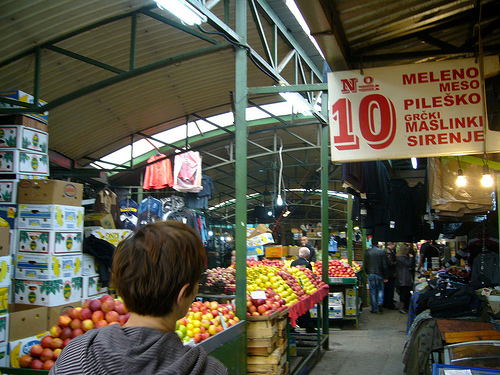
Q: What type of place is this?
A: It is a market.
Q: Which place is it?
A: It is a market.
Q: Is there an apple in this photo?
A: Yes, there are apples.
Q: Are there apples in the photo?
A: Yes, there are apples.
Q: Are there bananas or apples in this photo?
A: Yes, there are apples.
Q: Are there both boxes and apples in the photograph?
A: Yes, there are both apples and a box.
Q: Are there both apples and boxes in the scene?
A: Yes, there are both apples and a box.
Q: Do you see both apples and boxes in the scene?
A: Yes, there are both apples and a box.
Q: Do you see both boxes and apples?
A: Yes, there are both apples and a box.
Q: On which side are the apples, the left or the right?
A: The apples are on the left of the image.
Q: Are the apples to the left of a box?
A: Yes, the apples are to the left of a box.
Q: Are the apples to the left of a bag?
A: No, the apples are to the left of a box.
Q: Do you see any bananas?
A: Yes, there are bananas.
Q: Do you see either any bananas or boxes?
A: Yes, there are bananas.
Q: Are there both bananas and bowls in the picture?
A: No, there are bananas but no bowls.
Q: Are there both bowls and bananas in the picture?
A: No, there are bananas but no bowls.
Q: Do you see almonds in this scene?
A: No, there are no almonds.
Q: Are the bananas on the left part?
A: Yes, the bananas are on the left of the image.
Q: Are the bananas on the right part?
A: No, the bananas are on the left of the image.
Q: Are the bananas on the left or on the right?
A: The bananas are on the left of the image.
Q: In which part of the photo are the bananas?
A: The bananas are on the left of the image.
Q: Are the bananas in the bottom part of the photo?
A: Yes, the bananas are in the bottom of the image.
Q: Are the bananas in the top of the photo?
A: No, the bananas are in the bottom of the image.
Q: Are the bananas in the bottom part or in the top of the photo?
A: The bananas are in the bottom of the image.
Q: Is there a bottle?
A: No, there are no bottles.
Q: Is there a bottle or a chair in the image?
A: No, there are no bottles or chairs.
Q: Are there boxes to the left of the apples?
A: No, the box is to the right of the apples.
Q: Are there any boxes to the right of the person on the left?
A: Yes, there is a box to the right of the person.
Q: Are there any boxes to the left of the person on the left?
A: No, the box is to the right of the person.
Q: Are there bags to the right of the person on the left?
A: No, there is a box to the right of the person.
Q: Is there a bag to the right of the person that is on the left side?
A: No, there is a box to the right of the person.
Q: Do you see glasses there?
A: No, there are no glasses.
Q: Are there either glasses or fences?
A: No, there are no glasses or fences.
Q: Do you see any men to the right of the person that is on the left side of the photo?
A: Yes, there is a man to the right of the person.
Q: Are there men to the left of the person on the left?
A: No, the man is to the right of the person.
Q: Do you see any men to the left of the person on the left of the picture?
A: No, the man is to the right of the person.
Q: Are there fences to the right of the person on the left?
A: No, there is a man to the right of the person.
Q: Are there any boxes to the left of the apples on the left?
A: No, the box is to the right of the apples.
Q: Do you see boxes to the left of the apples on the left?
A: No, the box is to the right of the apples.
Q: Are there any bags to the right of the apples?
A: No, there is a box to the right of the apples.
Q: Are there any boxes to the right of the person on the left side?
A: Yes, there is a box to the right of the person.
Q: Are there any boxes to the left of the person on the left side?
A: No, the box is to the right of the person.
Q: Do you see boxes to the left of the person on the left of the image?
A: No, the box is to the right of the person.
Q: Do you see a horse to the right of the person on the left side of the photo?
A: No, there is a box to the right of the person.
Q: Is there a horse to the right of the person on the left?
A: No, there is a box to the right of the person.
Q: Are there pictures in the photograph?
A: No, there are no pictures.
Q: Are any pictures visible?
A: No, there are no pictures.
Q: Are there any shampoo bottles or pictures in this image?
A: No, there are no pictures or shampoo bottles.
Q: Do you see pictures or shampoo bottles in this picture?
A: No, there are no pictures or shampoo bottles.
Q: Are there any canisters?
A: No, there are no canisters.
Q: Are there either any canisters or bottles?
A: No, there are no canisters or bottles.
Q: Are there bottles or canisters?
A: No, there are no canisters or bottles.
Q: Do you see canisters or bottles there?
A: No, there are no canisters or bottles.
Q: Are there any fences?
A: No, there are no fences.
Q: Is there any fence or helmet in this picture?
A: No, there are no fences or helmets.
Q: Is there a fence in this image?
A: No, there are no fences.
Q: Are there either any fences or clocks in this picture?
A: No, there are no fences or clocks.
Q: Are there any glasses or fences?
A: No, there are no fences or glasses.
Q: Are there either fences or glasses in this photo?
A: No, there are no fences or glasses.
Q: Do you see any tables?
A: Yes, there is a table.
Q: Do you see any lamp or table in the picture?
A: Yes, there is a table.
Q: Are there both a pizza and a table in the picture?
A: No, there is a table but no pizzas.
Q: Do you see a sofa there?
A: No, there are no sofas.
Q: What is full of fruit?
A: The table is full of fruit.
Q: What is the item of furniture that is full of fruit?
A: The piece of furniture is a table.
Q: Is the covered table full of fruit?
A: Yes, the table is full of fruit.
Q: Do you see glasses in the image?
A: No, there are no glasses.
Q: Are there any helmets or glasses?
A: No, there are no glasses or helmets.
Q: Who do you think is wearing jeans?
A: The man is wearing jeans.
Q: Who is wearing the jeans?
A: The man is wearing jeans.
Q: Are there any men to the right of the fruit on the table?
A: Yes, there is a man to the right of the fruit.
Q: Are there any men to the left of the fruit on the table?
A: No, the man is to the right of the fruit.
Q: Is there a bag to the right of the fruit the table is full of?
A: No, there is a man to the right of the fruit.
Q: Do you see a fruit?
A: Yes, there is a fruit.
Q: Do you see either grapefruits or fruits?
A: Yes, there is a fruit.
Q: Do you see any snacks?
A: No, there are no snacks.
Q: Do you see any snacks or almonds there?
A: No, there are no snacks or almonds.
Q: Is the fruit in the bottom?
A: Yes, the fruit is in the bottom of the image.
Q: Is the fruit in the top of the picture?
A: No, the fruit is in the bottom of the image.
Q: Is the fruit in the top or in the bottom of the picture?
A: The fruit is in the bottom of the image.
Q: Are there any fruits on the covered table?
A: Yes, there is a fruit on the table.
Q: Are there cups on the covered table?
A: No, there is a fruit on the table.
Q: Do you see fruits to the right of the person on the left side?
A: Yes, there is a fruit to the right of the person.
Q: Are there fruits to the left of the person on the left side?
A: No, the fruit is to the right of the person.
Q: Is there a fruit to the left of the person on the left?
A: No, the fruit is to the right of the person.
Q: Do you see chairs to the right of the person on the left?
A: No, there is a fruit to the right of the person.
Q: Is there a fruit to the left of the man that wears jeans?
A: Yes, there is a fruit to the left of the man.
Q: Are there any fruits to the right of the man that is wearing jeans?
A: No, the fruit is to the left of the man.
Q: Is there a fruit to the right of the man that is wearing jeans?
A: No, the fruit is to the left of the man.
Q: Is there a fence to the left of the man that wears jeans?
A: No, there is a fruit to the left of the man.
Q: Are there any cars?
A: No, there are no cars.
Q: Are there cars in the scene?
A: No, there are no cars.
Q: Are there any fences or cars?
A: No, there are no cars or fences.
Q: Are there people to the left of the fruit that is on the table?
A: Yes, there is a person to the left of the fruit.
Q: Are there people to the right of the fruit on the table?
A: No, the person is to the left of the fruit.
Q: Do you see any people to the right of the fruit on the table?
A: No, the person is to the left of the fruit.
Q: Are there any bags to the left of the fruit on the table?
A: No, there is a person to the left of the fruit.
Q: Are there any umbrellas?
A: No, there are no umbrellas.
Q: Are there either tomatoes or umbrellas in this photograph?
A: No, there are no umbrellas or tomatoes.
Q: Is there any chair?
A: No, there are no chairs.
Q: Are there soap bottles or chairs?
A: No, there are no chairs or soap bottles.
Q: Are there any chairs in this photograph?
A: No, there are no chairs.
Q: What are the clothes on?
A: The clothes are on the table.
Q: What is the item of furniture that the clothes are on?
A: The piece of furniture is a table.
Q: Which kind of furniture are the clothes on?
A: The clothes are on the table.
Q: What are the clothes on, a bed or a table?
A: The clothes are on a table.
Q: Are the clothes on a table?
A: Yes, the clothes are on a table.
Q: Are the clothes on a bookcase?
A: No, the clothes are on a table.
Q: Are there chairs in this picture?
A: No, there are no chairs.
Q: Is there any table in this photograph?
A: Yes, there is a table.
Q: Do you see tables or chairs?
A: Yes, there is a table.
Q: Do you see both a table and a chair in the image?
A: No, there is a table but no chairs.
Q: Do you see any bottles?
A: No, there are no bottles.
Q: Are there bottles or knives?
A: No, there are no bottles or knives.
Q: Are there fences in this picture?
A: No, there are no fences.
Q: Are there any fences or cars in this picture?
A: No, there are no fences or cars.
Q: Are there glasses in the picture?
A: No, there are no glasses.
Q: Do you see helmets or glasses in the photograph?
A: No, there are no glasses or helmets.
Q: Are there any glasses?
A: No, there are no glasses.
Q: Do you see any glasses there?
A: No, there are no glasses.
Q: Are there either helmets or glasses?
A: No, there are no glasses or helmets.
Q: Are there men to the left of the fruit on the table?
A: No, the man is to the right of the fruit.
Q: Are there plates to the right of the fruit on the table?
A: No, there is a man to the right of the fruit.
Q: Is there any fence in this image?
A: No, there are no fences.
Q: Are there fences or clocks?
A: No, there are no fences or clocks.